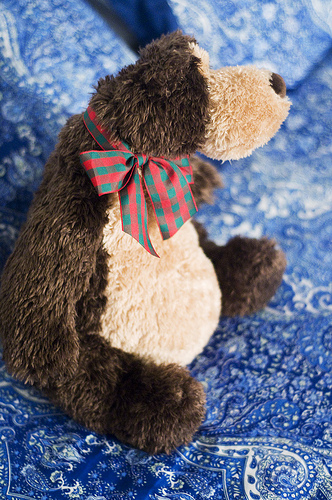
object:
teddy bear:
[0, 30, 291, 452]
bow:
[80, 112, 205, 246]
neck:
[66, 97, 210, 182]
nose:
[268, 72, 283, 97]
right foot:
[136, 361, 207, 453]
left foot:
[216, 235, 282, 323]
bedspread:
[0, 0, 332, 500]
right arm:
[11, 223, 88, 358]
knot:
[131, 150, 153, 171]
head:
[112, 35, 290, 167]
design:
[217, 355, 327, 499]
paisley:
[204, 345, 323, 497]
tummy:
[113, 253, 221, 359]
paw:
[161, 377, 205, 442]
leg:
[61, 333, 168, 461]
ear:
[134, 47, 189, 94]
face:
[185, 41, 294, 167]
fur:
[122, 56, 160, 122]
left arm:
[194, 153, 217, 200]